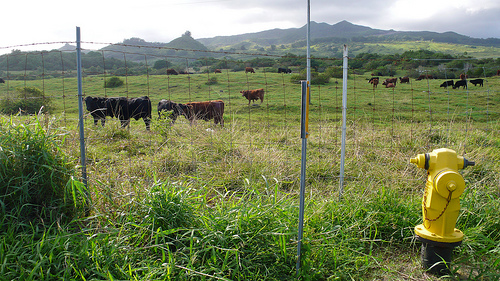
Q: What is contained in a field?
A: Cattle.